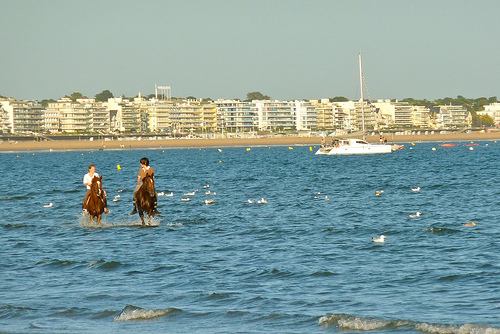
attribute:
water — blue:
[0, 139, 500, 333]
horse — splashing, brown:
[86, 174, 105, 224]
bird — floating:
[373, 233, 388, 243]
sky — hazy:
[1, 0, 500, 103]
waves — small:
[109, 304, 498, 332]